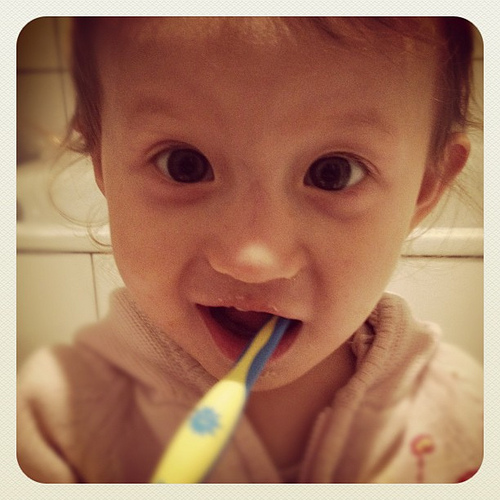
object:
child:
[15, 16, 483, 485]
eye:
[143, 141, 216, 186]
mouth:
[191, 302, 305, 371]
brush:
[147, 314, 292, 483]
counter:
[22, 196, 123, 297]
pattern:
[4, 214, 14, 278]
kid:
[16, 16, 484, 484]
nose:
[205, 201, 301, 285]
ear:
[407, 132, 471, 237]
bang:
[44, 50, 97, 158]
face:
[102, 57, 434, 391]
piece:
[311, 338, 425, 425]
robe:
[17, 286, 484, 483]